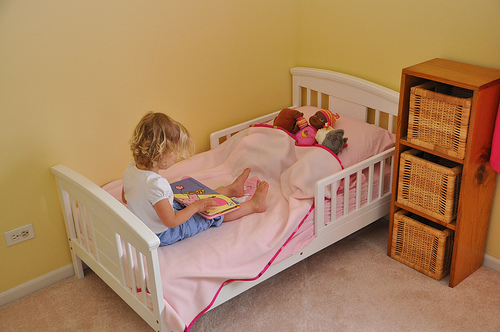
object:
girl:
[122, 112, 270, 247]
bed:
[51, 66, 399, 331]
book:
[169, 177, 241, 219]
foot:
[252, 179, 268, 213]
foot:
[233, 168, 251, 198]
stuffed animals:
[272, 106, 348, 151]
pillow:
[264, 104, 397, 169]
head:
[128, 110, 192, 170]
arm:
[159, 202, 197, 227]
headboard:
[289, 67, 400, 133]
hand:
[199, 197, 220, 208]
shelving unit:
[386, 57, 500, 288]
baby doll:
[297, 108, 339, 146]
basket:
[407, 87, 472, 160]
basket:
[398, 152, 461, 223]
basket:
[391, 210, 454, 281]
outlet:
[3, 222, 36, 248]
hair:
[129, 112, 194, 170]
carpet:
[0, 215, 500, 332]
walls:
[1, 0, 499, 294]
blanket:
[97, 123, 345, 330]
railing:
[313, 145, 394, 239]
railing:
[209, 104, 294, 150]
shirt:
[121, 164, 174, 234]